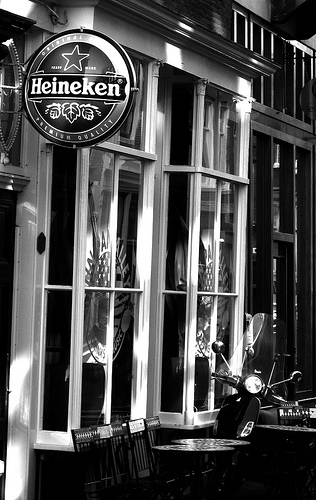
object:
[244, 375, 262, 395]
headlight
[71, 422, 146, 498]
seat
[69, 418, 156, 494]
back rest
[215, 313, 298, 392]
windshield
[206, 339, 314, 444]
bike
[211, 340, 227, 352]
mirror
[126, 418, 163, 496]
chair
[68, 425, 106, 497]
chair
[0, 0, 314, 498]
restaurant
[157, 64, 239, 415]
window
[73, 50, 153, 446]
window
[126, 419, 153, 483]
chair back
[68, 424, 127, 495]
chair back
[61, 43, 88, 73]
star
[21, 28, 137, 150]
sign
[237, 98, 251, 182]
trim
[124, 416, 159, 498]
chair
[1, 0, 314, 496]
building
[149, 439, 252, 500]
table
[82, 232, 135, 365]
logo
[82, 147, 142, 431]
pane